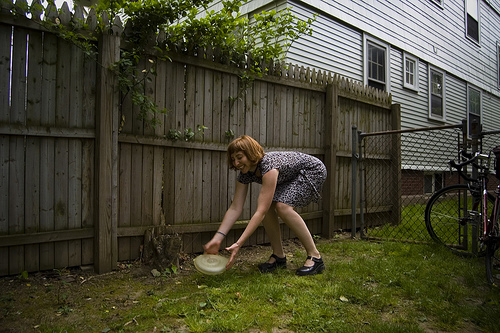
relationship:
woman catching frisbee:
[205, 134, 327, 277] [193, 253, 231, 273]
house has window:
[241, 0, 500, 201] [426, 66, 443, 118]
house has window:
[241, 0, 500, 201] [364, 37, 389, 83]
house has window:
[241, 0, 500, 201] [403, 56, 416, 86]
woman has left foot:
[205, 134, 327, 277] [296, 248, 328, 276]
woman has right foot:
[205, 134, 327, 277] [254, 247, 288, 275]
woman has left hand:
[205, 134, 327, 277] [221, 239, 239, 267]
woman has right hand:
[205, 134, 327, 277] [199, 236, 221, 254]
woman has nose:
[205, 134, 327, 277] [232, 158, 242, 167]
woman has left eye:
[205, 134, 327, 277] [236, 155, 247, 160]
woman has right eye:
[205, 134, 327, 277] [229, 154, 235, 164]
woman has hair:
[205, 134, 327, 277] [227, 136, 263, 165]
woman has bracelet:
[205, 134, 327, 277] [217, 227, 228, 240]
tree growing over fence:
[80, 1, 316, 141] [0, 1, 401, 276]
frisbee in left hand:
[193, 253, 231, 273] [221, 239, 239, 267]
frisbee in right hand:
[193, 253, 231, 273] [199, 236, 221, 254]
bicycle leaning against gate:
[424, 135, 498, 254] [351, 129, 468, 251]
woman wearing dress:
[205, 134, 327, 277] [235, 153, 328, 208]